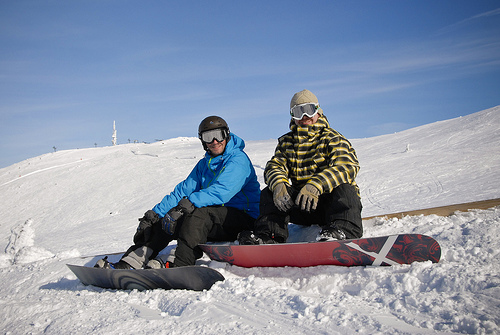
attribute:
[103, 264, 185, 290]
board — black, gray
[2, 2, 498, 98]
blue sky — daytime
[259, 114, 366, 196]
jacket — yellow, plaid, snow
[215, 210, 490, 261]
board — red, black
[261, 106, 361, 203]
jacket — black, yellow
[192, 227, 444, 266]
snowboard — red, black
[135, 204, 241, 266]
snow pants — black 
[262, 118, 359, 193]
coat —  yellow ,  black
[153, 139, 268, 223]
jacket — blue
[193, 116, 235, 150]
helmet — black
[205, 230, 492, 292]
snowboard — red, white, black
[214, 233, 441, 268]
snowboard — sideways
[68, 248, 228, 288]
snowboard — sideways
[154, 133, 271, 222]
jacket — blue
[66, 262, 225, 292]
snowboard — gray and blue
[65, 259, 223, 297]
snowboard — black, gray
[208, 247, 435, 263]
snowboard — bottom